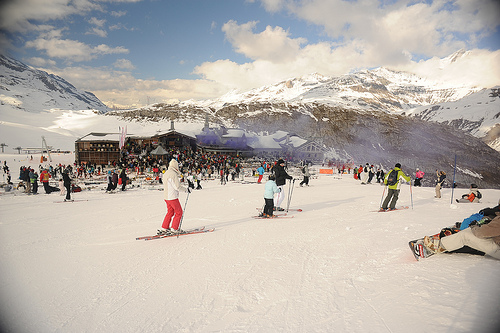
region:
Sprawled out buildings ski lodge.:
[69, 118, 331, 172]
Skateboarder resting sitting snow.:
[399, 215, 499, 267]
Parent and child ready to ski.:
[259, 147, 306, 232]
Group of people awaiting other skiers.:
[7, 151, 156, 202]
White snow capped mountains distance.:
[241, 50, 499, 132]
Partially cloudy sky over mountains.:
[43, 9, 348, 116]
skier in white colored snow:
[154, 151, 194, 224]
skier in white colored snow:
[255, 151, 295, 200]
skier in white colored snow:
[376, 153, 406, 204]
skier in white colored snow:
[417, 160, 432, 195]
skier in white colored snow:
[428, 161, 450, 198]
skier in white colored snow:
[53, 154, 75, 194]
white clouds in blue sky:
[175, 24, 211, 56]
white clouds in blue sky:
[318, 23, 372, 50]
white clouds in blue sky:
[37, 16, 88, 50]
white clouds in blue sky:
[400, 21, 472, 56]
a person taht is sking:
[146, 149, 196, 240]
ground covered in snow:
[208, 249, 390, 321]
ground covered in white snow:
[244, 212, 357, 316]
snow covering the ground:
[225, 227, 394, 330]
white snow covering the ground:
[187, 215, 411, 327]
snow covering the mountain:
[257, 37, 498, 183]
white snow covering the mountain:
[251, 68, 494, 183]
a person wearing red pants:
[167, 192, 181, 238]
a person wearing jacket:
[139, 159, 189, 227]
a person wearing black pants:
[249, 170, 281, 230]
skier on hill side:
[135, 151, 196, 238]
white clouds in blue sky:
[421, 12, 481, 76]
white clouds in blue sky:
[211, 5, 258, 36]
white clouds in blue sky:
[115, 58, 152, 78]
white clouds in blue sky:
[52, 15, 109, 46]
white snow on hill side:
[242, 252, 297, 286]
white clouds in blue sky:
[102, 36, 179, 74]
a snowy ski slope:
[0, 151, 499, 331]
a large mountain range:
[0, 46, 498, 188]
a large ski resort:
[72, 120, 328, 165]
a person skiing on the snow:
[156, 158, 193, 233]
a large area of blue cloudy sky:
[0, 0, 499, 110]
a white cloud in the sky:
[220, 18, 307, 63]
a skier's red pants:
[160, 198, 182, 230]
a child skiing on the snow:
[261, 173, 281, 216]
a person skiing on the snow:
[380, 162, 411, 209]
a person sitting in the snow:
[455, 183, 481, 203]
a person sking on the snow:
[151, 150, 216, 266]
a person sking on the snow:
[265, 172, 285, 216]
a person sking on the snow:
[271, 149, 294, 215]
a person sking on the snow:
[390, 154, 410, 211]